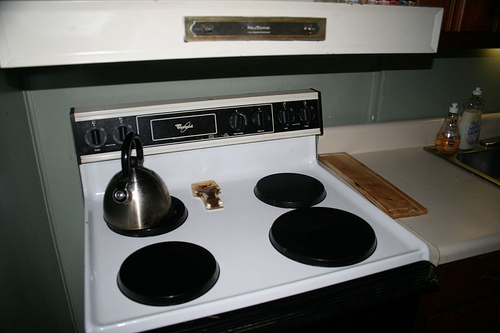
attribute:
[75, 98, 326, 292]
stove — white, black, gas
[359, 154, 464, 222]
counter — white, brown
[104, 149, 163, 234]
kettle — silver, whistling, steel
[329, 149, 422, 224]
board — for chopping, wooden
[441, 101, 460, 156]
bottle — plastic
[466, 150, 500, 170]
sink — silver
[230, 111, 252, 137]
knob — black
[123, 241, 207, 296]
burner — large, circular, black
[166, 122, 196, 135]
logo — white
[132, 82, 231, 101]
wall — green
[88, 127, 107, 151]
dial — black